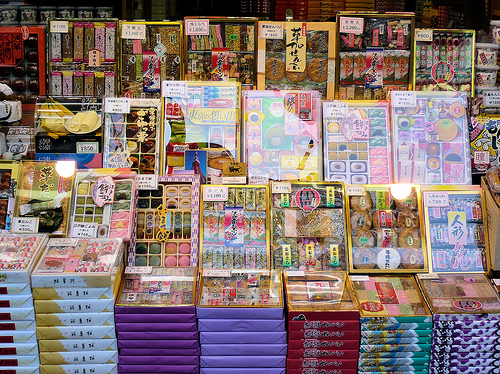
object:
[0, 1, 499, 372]
stand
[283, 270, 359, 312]
cover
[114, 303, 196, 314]
paper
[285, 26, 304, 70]
writing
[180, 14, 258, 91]
gift box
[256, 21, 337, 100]
gift box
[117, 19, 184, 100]
package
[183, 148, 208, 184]
card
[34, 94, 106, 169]
box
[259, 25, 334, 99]
top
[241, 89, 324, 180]
middle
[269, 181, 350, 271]
bottom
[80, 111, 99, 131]
candies